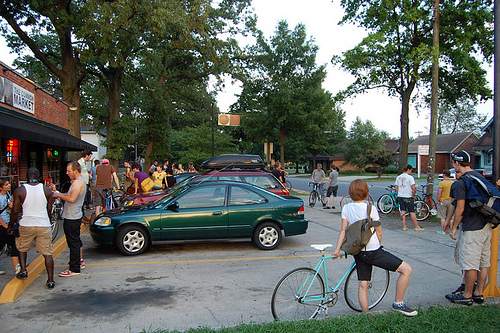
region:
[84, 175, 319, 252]
green two door car parked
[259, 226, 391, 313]
light blue bike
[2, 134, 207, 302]
a group of people outside the store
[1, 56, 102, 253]
the local market store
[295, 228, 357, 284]
a bike with a white seat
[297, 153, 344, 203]
two people wearing grey shirts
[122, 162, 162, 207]
people sitting on a car in the parking lot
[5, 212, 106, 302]
a curb painted yellow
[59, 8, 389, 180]
lots of tall green trees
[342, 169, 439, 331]
lady standing with one foot on the curb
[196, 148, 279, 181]
A hard shell luggage carrier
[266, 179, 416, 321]
A person leaning on a light blue bike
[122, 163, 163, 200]
A woman in a purple shirt leaning on a car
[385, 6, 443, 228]
Bikes leaning on a pole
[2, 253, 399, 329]
A parking spot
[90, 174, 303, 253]
A green two door car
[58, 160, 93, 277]
A man in a gray tank and black pants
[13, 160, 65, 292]
A man in a white tank and khaki shorts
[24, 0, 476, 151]
Trees with green leaves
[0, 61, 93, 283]
The front of a market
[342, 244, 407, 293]
a pair of black shorts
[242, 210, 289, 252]
a black car tire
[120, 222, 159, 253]
the front car tire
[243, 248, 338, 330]
the back bike tire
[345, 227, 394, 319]
the front bike tire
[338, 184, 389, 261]
a brown messenger bag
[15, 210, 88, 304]
a yellow car curb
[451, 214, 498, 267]
a guy's khaki shorts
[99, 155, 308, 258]
a green colored sedan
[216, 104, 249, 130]
a small orange flag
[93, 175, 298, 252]
a green car in background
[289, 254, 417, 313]
a blue bike in background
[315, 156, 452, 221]
a group of bikes parked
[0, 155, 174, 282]
a group of people going to the store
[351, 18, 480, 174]
big green tree in background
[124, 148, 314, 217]
a red car parked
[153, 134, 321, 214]
a boat on the red car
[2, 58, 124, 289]
a store where people shop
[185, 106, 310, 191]
a store sign in the background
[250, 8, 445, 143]
a bright clear sky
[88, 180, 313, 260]
A GREEN CAR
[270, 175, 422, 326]
A PERSON WITH A BLUE BIKE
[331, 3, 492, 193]
TREES IN THE BACKGROUND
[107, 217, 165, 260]
FRONT TIRE OF A CAR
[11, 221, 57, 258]
A PAIR OF SHORTS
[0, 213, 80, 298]
A CURB PAINTED YELLOW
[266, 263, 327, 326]
REAR BIKE WHEEL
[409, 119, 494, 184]
HOUSES IN THE DISTANCE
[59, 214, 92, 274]
BLACK PANTS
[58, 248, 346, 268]
YELLOW LINE ON THE PAVEMENT